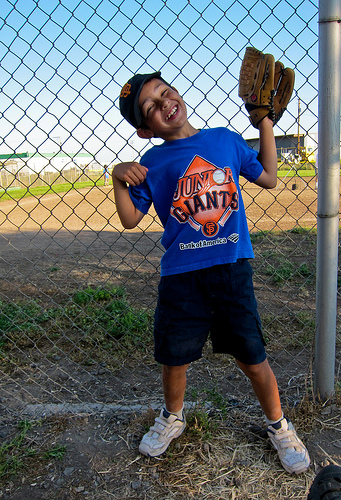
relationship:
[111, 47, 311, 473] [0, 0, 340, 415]
boy standing in front of fence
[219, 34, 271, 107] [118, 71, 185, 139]
hat on boy's head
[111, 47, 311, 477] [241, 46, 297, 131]
boy has a baseball glove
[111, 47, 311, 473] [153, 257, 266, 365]
boy wearing shorts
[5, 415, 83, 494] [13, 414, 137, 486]
grass in dirt